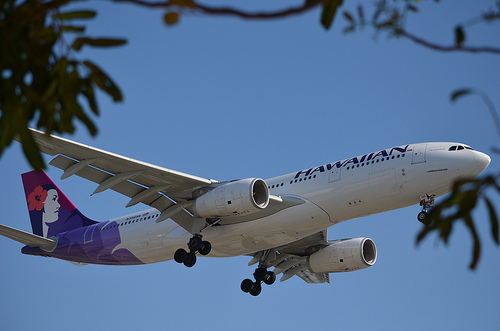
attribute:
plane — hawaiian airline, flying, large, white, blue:
[1, 117, 492, 297]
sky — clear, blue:
[1, 1, 497, 327]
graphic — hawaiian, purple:
[11, 163, 144, 275]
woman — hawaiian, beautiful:
[26, 182, 63, 239]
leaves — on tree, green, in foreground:
[0, 0, 495, 271]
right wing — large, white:
[14, 123, 217, 236]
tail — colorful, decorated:
[16, 166, 101, 240]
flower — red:
[27, 183, 49, 209]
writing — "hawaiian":
[292, 144, 410, 177]